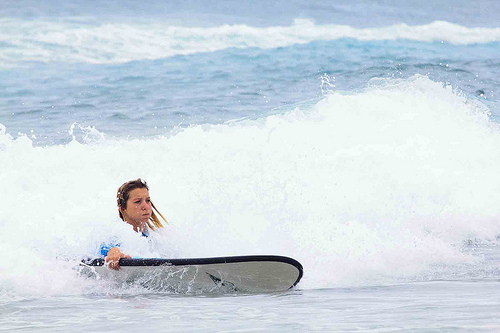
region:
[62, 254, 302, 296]
black and white surfboard in the water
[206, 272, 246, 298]
black logo on white surfboard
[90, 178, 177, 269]
woman on top of surfboard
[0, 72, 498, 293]
large wave behind woman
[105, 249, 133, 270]
hand on surfboard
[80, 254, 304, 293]
edge of surfboard is black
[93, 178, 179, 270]
woman is wet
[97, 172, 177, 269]
woman is in the water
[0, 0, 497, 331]
water is blue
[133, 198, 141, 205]
eyes on woman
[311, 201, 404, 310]
The water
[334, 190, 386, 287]
The water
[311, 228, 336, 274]
The water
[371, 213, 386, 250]
The water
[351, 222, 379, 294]
The water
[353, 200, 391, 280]
The water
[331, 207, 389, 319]
The water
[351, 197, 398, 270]
The water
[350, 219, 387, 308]
The water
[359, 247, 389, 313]
The water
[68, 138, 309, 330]
A woman is surfboarding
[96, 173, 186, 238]
Woman has long brown hair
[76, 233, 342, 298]
Woman's surfboard is gray and black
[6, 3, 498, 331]
Photo was taken outdoors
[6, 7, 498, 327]
Photo was taken in the daytime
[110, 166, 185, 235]
Woman's hair is wet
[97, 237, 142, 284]
Woman's hand is in the surfboard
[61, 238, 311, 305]
A black ring is around the surfboard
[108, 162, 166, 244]
Woman is looking to her left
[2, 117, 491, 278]
A wave of water is behind the woman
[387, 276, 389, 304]
The water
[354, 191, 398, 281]
The water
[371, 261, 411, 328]
The water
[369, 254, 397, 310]
The water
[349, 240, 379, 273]
The water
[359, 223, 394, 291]
The water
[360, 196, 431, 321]
The water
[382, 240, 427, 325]
The water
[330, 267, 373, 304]
The water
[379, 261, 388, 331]
The water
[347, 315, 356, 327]
the sea water is clear white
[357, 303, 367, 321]
the sea water is clear white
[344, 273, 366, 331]
the sea water is clear white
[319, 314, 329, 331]
the sea water is clear white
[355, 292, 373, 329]
the sea water is clear white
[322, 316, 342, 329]
the sea water is clear white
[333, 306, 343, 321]
the sea water is clear white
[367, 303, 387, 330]
the sea water is clear white